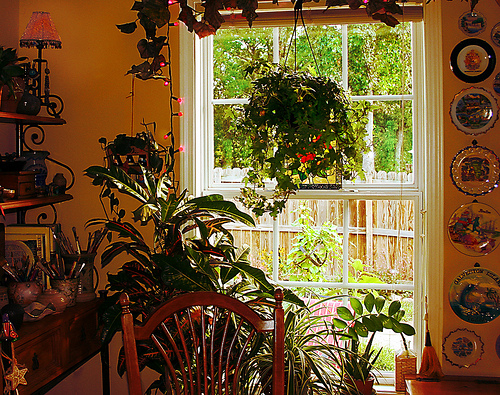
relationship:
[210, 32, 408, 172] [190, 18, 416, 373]
trees growing outside window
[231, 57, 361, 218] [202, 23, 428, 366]
hanging plant hanging in front of window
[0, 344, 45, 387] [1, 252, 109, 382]
star decoration on table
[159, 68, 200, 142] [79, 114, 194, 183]
lights on plant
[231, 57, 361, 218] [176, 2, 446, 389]
hanging plant in front of a window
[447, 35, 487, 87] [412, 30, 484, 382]
plate hanging on th wall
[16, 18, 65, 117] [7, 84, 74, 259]
lamp on top shelf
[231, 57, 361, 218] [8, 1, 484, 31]
hanging plant hanging cieling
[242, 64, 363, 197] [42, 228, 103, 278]
flowers in flowers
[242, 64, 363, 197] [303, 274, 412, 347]
flowers in flowers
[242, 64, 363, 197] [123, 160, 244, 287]
flowers in flowers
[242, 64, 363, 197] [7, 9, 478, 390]
flowers in photo